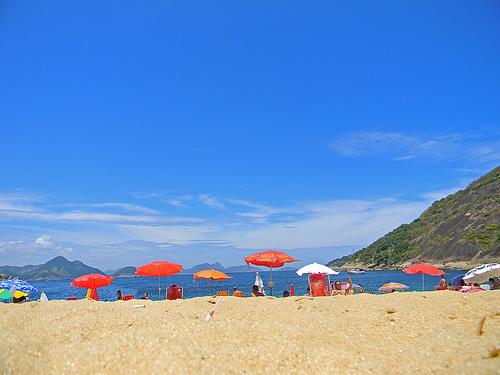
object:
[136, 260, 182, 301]
umbrella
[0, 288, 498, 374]
beach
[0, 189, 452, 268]
clouds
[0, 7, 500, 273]
sky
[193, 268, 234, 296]
umbrella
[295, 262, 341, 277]
umbrella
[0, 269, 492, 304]
ocean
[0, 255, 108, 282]
mountain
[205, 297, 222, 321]
cigarette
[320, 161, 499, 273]
mountain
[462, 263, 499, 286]
umbrella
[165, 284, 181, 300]
person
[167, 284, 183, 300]
chair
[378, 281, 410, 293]
umbrella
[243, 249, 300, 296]
umbrella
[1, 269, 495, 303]
water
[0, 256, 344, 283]
mountains